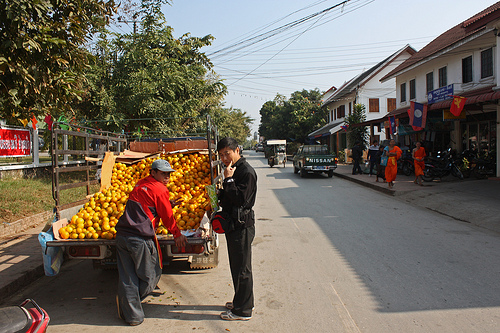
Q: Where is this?
A: This is at the street.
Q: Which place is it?
A: It is a street.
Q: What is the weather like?
A: It is clear.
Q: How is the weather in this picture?
A: It is clear.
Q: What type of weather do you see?
A: It is clear.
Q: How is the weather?
A: It is clear.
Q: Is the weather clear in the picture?
A: Yes, it is clear.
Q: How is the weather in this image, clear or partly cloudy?
A: It is clear.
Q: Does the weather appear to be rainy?
A: No, it is clear.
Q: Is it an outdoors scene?
A: Yes, it is outdoors.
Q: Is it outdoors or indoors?
A: It is outdoors.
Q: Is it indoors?
A: No, it is outdoors.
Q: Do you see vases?
A: No, there are no vases.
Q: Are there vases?
A: No, there are no vases.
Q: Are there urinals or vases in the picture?
A: No, there are no vases or urinals.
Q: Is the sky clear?
A: Yes, the sky is clear.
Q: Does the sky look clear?
A: Yes, the sky is clear.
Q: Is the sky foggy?
A: No, the sky is clear.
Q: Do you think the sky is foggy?
A: No, the sky is clear.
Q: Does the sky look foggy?
A: No, the sky is clear.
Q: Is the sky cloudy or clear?
A: The sky is clear.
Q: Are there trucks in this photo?
A: Yes, there is a truck.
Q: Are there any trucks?
A: Yes, there is a truck.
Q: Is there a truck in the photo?
A: Yes, there is a truck.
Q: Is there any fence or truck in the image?
A: Yes, there is a truck.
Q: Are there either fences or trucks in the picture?
A: Yes, there is a truck.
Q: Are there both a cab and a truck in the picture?
A: No, there is a truck but no taxis.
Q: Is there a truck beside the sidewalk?
A: Yes, there is a truck beside the sidewalk.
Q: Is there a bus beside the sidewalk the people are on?
A: No, there is a truck beside the sidewalk.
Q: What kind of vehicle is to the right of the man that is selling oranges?
A: The vehicle is a truck.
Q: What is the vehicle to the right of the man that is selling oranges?
A: The vehicle is a truck.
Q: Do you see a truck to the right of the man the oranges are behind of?
A: Yes, there is a truck to the right of the man.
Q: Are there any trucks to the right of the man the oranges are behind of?
A: Yes, there is a truck to the right of the man.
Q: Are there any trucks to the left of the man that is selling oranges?
A: No, the truck is to the right of the man.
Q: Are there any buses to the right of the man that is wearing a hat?
A: No, there is a truck to the right of the man.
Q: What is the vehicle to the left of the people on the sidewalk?
A: The vehicle is a truck.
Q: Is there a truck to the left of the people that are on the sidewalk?
A: Yes, there is a truck to the left of the people.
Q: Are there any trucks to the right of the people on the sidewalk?
A: No, the truck is to the left of the people.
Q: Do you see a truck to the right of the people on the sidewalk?
A: No, the truck is to the left of the people.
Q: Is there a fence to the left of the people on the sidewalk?
A: No, there is a truck to the left of the people.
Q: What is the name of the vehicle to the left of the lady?
A: The vehicle is a truck.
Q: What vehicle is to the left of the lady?
A: The vehicle is a truck.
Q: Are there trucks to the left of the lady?
A: Yes, there is a truck to the left of the lady.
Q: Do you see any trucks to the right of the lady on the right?
A: No, the truck is to the left of the lady.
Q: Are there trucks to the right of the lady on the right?
A: No, the truck is to the left of the lady.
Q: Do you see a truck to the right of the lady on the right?
A: No, the truck is to the left of the lady.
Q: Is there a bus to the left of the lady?
A: No, there is a truck to the left of the lady.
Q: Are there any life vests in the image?
A: No, there are no life vests.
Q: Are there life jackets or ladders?
A: No, there are no life jackets or ladders.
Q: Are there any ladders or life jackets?
A: No, there are no life jackets or ladders.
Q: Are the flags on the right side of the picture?
A: Yes, the flags are on the right of the image.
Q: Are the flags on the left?
A: No, the flags are on the right of the image.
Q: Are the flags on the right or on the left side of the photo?
A: The flags are on the right of the image.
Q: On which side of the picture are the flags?
A: The flags are on the right of the image.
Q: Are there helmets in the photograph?
A: No, there are no helmets.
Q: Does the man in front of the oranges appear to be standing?
A: Yes, the man is standing.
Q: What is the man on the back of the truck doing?
A: The man is standing.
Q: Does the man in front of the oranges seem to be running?
A: No, the man is standing.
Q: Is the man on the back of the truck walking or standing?
A: The man is standing.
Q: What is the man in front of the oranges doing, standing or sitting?
A: The man is standing.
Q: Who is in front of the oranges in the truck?
A: The man is in front of the oranges.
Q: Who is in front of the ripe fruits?
A: The man is in front of the oranges.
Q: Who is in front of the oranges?
A: The man is in front of the oranges.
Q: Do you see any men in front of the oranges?
A: Yes, there is a man in front of the oranges.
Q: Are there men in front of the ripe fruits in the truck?
A: Yes, there is a man in front of the oranges.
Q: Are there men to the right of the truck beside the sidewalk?
A: No, the man is to the left of the truck.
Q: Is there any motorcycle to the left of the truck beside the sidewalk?
A: No, there is a man to the left of the truck.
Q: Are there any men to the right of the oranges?
A: Yes, there is a man to the right of the oranges.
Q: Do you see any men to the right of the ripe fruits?
A: Yes, there is a man to the right of the oranges.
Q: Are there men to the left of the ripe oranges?
A: No, the man is to the right of the oranges.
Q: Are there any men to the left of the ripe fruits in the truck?
A: No, the man is to the right of the oranges.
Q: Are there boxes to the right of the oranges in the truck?
A: No, there is a man to the right of the oranges.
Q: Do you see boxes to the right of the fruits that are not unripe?
A: No, there is a man to the right of the oranges.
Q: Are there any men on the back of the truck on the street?
A: Yes, there is a man on the back of the truck.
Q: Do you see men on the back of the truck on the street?
A: Yes, there is a man on the back of the truck.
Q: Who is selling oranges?
A: The man is selling oranges.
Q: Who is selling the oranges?
A: The man is selling oranges.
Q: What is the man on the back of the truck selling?
A: The man is selling oranges.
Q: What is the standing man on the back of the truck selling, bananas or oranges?
A: The man is selling oranges.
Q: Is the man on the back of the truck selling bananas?
A: No, the man is selling oranges.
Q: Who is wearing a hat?
A: The man is wearing a hat.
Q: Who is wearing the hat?
A: The man is wearing a hat.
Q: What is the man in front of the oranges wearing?
A: The man is wearing a hat.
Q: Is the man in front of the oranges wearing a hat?
A: Yes, the man is wearing a hat.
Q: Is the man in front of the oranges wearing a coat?
A: No, the man is wearing a hat.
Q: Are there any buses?
A: No, there are no buses.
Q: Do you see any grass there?
A: Yes, there is grass.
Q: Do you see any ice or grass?
A: Yes, there is grass.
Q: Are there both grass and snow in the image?
A: No, there is grass but no snow.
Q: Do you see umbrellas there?
A: No, there are no umbrellas.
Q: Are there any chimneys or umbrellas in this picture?
A: No, there are no umbrellas or chimneys.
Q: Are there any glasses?
A: No, there are no glasses.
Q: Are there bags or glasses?
A: No, there are no glasses or bags.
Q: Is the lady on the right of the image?
A: Yes, the lady is on the right of the image.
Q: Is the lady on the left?
A: No, the lady is on the right of the image.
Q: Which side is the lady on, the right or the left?
A: The lady is on the right of the image.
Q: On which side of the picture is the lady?
A: The lady is on the right of the image.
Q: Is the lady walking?
A: Yes, the lady is walking.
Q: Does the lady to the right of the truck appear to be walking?
A: Yes, the lady is walking.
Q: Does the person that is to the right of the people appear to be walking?
A: Yes, the lady is walking.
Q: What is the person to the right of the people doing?
A: The lady is walking.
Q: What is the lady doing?
A: The lady is walking.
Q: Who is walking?
A: The lady is walking.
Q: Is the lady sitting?
A: No, the lady is walking.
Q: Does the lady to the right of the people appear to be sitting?
A: No, the lady is walking.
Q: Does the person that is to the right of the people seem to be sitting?
A: No, the lady is walking.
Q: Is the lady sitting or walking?
A: The lady is walking.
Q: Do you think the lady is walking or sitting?
A: The lady is walking.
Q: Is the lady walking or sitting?
A: The lady is walking.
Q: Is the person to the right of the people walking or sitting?
A: The lady is walking.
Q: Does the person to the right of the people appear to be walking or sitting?
A: The lady is walking.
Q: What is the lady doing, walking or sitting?
A: The lady is walking.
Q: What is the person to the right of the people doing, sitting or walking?
A: The lady is walking.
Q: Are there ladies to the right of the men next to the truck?
A: Yes, there is a lady to the right of the men.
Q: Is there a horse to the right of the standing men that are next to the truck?
A: No, there is a lady to the right of the men.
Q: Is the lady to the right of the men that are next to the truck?
A: Yes, the lady is to the right of the men.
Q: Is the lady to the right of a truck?
A: Yes, the lady is to the right of a truck.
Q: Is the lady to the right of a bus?
A: No, the lady is to the right of a truck.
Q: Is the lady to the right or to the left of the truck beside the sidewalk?
A: The lady is to the right of the truck.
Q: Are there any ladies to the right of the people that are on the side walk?
A: Yes, there is a lady to the right of the people.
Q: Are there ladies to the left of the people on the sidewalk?
A: No, the lady is to the right of the people.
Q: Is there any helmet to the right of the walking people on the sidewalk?
A: No, there is a lady to the right of the people.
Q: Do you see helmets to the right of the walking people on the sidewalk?
A: No, there is a lady to the right of the people.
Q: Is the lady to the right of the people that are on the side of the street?
A: Yes, the lady is to the right of the people.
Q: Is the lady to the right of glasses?
A: No, the lady is to the right of the people.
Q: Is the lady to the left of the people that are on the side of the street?
A: No, the lady is to the right of the people.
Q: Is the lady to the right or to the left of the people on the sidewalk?
A: The lady is to the right of the people.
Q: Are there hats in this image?
A: Yes, there is a hat.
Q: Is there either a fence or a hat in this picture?
A: Yes, there is a hat.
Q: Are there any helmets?
A: No, there are no helmets.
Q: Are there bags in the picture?
A: No, there are no bags.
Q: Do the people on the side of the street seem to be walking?
A: Yes, the people are walking.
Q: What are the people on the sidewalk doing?
A: The people are walking.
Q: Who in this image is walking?
A: The people are walking.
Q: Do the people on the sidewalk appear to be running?
A: No, the people are walking.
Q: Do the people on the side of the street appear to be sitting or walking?
A: The people are walking.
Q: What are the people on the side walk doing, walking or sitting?
A: The people are walking.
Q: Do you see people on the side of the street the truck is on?
A: Yes, there are people on the side of the street.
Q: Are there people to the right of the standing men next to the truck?
A: Yes, there are people to the right of the men.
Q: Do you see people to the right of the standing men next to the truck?
A: Yes, there are people to the right of the men.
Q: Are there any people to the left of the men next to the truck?
A: No, the people are to the right of the men.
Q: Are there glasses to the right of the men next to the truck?
A: No, there are people to the right of the men.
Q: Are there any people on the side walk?
A: Yes, there are people on the side walk.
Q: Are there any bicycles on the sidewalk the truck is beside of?
A: No, there are people on the sidewalk.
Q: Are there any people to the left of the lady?
A: Yes, there are people to the left of the lady.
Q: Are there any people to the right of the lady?
A: No, the people are to the left of the lady.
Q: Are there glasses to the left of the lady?
A: No, there are people to the left of the lady.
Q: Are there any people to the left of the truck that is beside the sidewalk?
A: No, the people are to the right of the truck.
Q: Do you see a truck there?
A: Yes, there is a truck.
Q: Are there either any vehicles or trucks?
A: Yes, there is a truck.